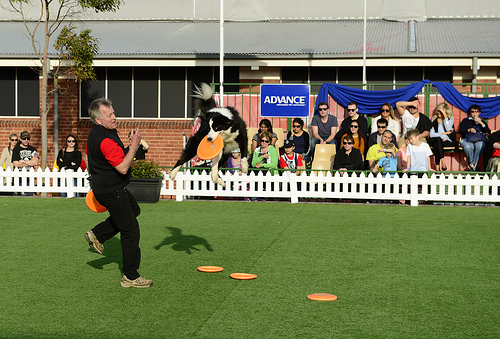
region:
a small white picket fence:
[196, 170, 489, 212]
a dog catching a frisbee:
[170, 91, 241, 176]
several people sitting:
[245, 90, 477, 190]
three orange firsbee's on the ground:
[195, 252, 345, 307]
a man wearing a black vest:
[56, 83, 157, 270]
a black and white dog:
[168, 87, 254, 192]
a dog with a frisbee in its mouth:
[176, 88, 258, 182]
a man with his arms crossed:
[11, 125, 36, 180]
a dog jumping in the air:
[174, 87, 274, 198]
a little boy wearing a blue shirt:
[367, 134, 395, 179]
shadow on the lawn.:
[163, 210, 220, 250]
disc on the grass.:
[302, 287, 338, 313]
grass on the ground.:
[228, 305, 264, 325]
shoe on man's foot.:
[117, 275, 154, 293]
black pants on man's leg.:
[120, 207, 137, 265]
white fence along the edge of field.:
[246, 180, 371, 196]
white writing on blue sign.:
[260, 87, 309, 114]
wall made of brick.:
[155, 135, 177, 153]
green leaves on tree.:
[67, 38, 93, 64]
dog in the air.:
[208, 100, 248, 142]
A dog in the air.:
[165, 84, 255, 186]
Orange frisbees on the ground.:
[195, 256, 348, 312]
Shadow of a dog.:
[152, 221, 217, 265]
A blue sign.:
[258, 82, 310, 119]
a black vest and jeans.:
[87, 123, 150, 276]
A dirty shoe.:
[117, 270, 155, 290]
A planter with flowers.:
[124, 156, 168, 201]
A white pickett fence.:
[235, 171, 498, 208]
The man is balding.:
[86, 96, 117, 132]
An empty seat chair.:
[308, 143, 335, 179]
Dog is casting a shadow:
[153, 211, 220, 265]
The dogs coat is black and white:
[170, 81, 260, 180]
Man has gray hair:
[71, 84, 122, 126]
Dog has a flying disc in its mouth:
[187, 118, 241, 173]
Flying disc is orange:
[177, 129, 234, 171]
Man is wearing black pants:
[76, 183, 163, 283]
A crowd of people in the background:
[231, 94, 498, 186]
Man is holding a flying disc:
[77, 180, 117, 217]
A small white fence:
[2, 161, 497, 213]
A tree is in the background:
[12, 1, 120, 178]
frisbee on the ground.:
[298, 287, 338, 309]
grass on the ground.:
[417, 247, 462, 289]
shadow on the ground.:
[156, 219, 208, 260]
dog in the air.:
[169, 112, 241, 181]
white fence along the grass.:
[237, 175, 349, 207]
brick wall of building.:
[159, 132, 176, 148]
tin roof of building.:
[127, 31, 207, 57]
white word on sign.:
[262, 84, 306, 114]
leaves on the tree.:
[66, 35, 86, 60]